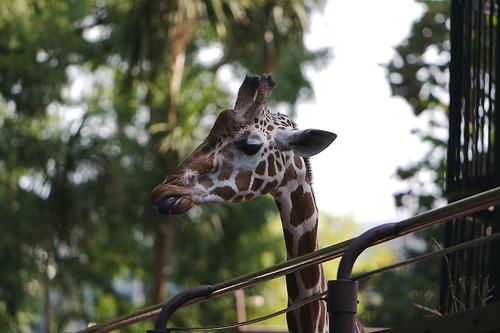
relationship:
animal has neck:
[152, 65, 326, 332] [271, 140, 332, 330]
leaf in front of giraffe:
[33, 104, 138, 233] [161, 79, 431, 289]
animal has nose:
[152, 65, 326, 332] [135, 171, 180, 205]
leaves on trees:
[386, 3, 447, 115] [227, 0, 326, 77]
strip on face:
[166, 131, 222, 183] [149, 107, 279, 214]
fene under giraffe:
[1, 183, 498, 330] [141, 55, 323, 243]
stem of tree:
[113, 58, 211, 225] [142, 0, 212, 327]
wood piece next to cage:
[233, 287, 282, 332] [394, 67, 491, 257]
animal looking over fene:
[152, 65, 326, 332] [1, 183, 498, 330]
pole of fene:
[318, 232, 365, 328] [1, 183, 498, 330]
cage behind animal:
[435, 2, 498, 315] [152, 65, 326, 332]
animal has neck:
[152, 65, 326, 332] [274, 179, 342, 331]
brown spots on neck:
[285, 218, 317, 317] [274, 179, 342, 331]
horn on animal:
[208, 62, 272, 99] [152, 65, 326, 332]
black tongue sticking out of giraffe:
[156, 198, 176, 216] [142, 43, 337, 331]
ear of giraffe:
[275, 127, 335, 156] [105, 105, 363, 282]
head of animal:
[144, 69, 334, 220] [152, 65, 326, 332]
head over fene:
[144, 69, 334, 220] [1, 183, 498, 330]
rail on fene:
[401, 175, 498, 236] [1, 183, 498, 330]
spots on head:
[213, 160, 280, 205] [144, 69, 334, 220]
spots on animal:
[213, 160, 280, 205] [152, 65, 326, 332]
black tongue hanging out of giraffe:
[140, 178, 198, 230] [137, 89, 351, 301]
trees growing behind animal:
[1, 0, 336, 332] [152, 65, 326, 332]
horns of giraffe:
[214, 73, 294, 117] [85, 52, 362, 304]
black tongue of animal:
[156, 198, 176, 216] [152, 65, 326, 332]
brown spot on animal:
[231, 170, 256, 194] [152, 65, 326, 332]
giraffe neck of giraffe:
[269, 185, 329, 333] [103, 80, 420, 331]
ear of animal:
[275, 127, 335, 156] [152, 65, 326, 332]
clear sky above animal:
[300, 0, 420, 219] [152, 65, 326, 331]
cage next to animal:
[435, 2, 498, 315] [152, 65, 326, 332]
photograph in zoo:
[145, 46, 339, 332] [56, 71, 423, 331]